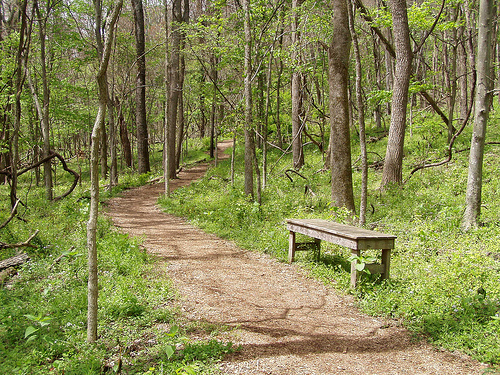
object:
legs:
[347, 247, 399, 293]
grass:
[438, 309, 493, 359]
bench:
[284, 215, 396, 295]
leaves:
[0, 0, 42, 151]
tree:
[389, 0, 415, 191]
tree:
[329, 0, 357, 212]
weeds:
[344, 250, 381, 280]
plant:
[19, 309, 61, 360]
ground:
[0, 138, 499, 373]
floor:
[149, 74, 189, 145]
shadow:
[212, 317, 427, 361]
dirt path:
[101, 149, 490, 374]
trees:
[70, 16, 114, 342]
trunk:
[376, 1, 413, 193]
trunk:
[322, 0, 354, 220]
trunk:
[459, 0, 496, 237]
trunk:
[156, 0, 201, 208]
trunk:
[286, 0, 307, 181]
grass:
[433, 280, 489, 332]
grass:
[109, 285, 140, 327]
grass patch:
[197, 195, 274, 228]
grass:
[45, 228, 71, 282]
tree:
[155, 5, 184, 209]